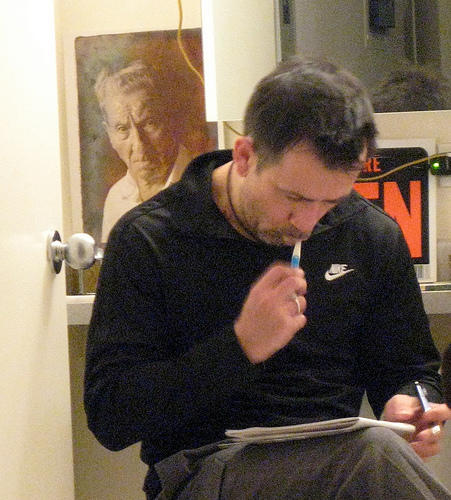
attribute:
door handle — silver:
[45, 226, 106, 273]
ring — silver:
[292, 297, 301, 313]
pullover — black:
[63, 151, 434, 428]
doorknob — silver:
[47, 230, 102, 274]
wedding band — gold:
[292, 296, 301, 315]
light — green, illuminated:
[418, 143, 449, 182]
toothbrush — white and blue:
[290, 237, 304, 268]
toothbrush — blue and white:
[290, 238, 302, 269]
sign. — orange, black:
[342, 99, 448, 272]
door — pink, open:
[13, 28, 119, 449]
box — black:
[429, 153, 450, 176]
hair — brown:
[241, 90, 323, 161]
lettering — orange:
[364, 158, 436, 278]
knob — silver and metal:
[52, 218, 122, 342]